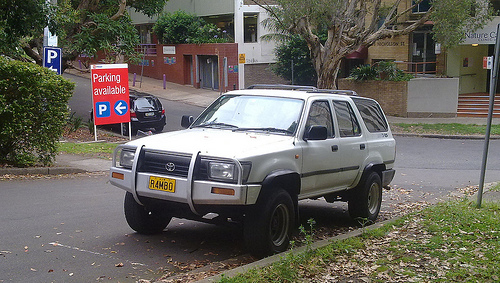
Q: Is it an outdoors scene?
A: Yes, it is outdoors.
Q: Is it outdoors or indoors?
A: It is outdoors.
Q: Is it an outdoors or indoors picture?
A: It is outdoors.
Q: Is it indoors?
A: No, it is outdoors.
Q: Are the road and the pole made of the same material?
A: No, the road is made of concrete and the pole is made of metal.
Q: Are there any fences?
A: No, there are no fences.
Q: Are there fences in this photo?
A: No, there are no fences.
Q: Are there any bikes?
A: No, there are no bikes.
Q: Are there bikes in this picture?
A: No, there are no bikes.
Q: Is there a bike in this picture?
A: No, there are no bikes.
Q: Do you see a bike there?
A: No, there are no bikes.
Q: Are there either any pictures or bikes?
A: No, there are no bikes or pictures.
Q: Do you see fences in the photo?
A: No, there are no fences.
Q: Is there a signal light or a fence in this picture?
A: No, there are no fences or traffic lights.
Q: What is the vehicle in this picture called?
A: The vehicle is a SUV.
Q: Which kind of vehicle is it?
A: The vehicle is a SUV.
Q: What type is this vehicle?
A: This is a SUV.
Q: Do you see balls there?
A: No, there are no balls.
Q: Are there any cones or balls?
A: No, there are no balls or cones.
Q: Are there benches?
A: No, there are no benches.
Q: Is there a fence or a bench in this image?
A: No, there are no benches or fences.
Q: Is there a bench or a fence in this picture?
A: No, there are no benches or fences.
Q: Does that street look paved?
A: Yes, the street is paved.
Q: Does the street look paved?
A: Yes, the street is paved.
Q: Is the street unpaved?
A: No, the street is paved.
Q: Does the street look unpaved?
A: No, the street is paved.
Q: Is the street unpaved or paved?
A: The street is paved.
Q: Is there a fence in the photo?
A: No, there are no fences.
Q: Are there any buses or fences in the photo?
A: No, there are no fences or buses.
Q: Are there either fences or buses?
A: No, there are no fences or buses.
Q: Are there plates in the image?
A: Yes, there is a plate.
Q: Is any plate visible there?
A: Yes, there is a plate.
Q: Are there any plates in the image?
A: Yes, there is a plate.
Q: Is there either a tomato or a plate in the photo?
A: Yes, there is a plate.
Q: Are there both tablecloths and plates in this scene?
A: No, there is a plate but no tablecloths.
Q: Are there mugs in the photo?
A: No, there are no mugs.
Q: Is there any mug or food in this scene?
A: No, there are no mugs or food.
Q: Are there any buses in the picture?
A: No, there are no buses.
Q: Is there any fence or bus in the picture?
A: No, there are no buses or fences.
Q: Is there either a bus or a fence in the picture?
A: No, there are no buses or fences.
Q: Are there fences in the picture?
A: No, there are no fences.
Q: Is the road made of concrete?
A: Yes, the road is made of concrete.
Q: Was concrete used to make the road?
A: Yes, the road is made of concrete.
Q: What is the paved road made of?
A: The road is made of concrete.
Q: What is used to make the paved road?
A: The road is made of concrete.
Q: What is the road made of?
A: The road is made of concrete.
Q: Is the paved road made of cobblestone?
A: No, the road is made of concrete.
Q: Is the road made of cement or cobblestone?
A: The road is made of cement.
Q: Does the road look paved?
A: Yes, the road is paved.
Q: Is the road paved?
A: Yes, the road is paved.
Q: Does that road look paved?
A: Yes, the road is paved.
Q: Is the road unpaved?
A: No, the road is paved.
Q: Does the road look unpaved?
A: No, the road is paved.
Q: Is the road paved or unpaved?
A: The road is paved.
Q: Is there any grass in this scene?
A: Yes, there is grass.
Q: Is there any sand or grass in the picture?
A: Yes, there is grass.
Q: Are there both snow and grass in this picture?
A: No, there is grass but no snow.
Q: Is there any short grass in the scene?
A: Yes, there is short grass.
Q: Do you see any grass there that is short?
A: Yes, there is grass that is short.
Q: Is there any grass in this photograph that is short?
A: Yes, there is grass that is short.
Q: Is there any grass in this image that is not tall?
A: Yes, there is short grass.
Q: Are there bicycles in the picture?
A: No, there are no bicycles.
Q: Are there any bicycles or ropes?
A: No, there are no bicycles or ropes.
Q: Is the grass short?
A: Yes, the grass is short.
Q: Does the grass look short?
A: Yes, the grass is short.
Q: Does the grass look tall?
A: No, the grass is short.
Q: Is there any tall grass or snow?
A: No, there is grass but it is short.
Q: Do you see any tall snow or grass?
A: No, there is grass but it is short.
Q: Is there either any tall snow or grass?
A: No, there is grass but it is short.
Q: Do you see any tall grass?
A: No, there is grass but it is short.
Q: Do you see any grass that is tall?
A: No, there is grass but it is short.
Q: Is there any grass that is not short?
A: No, there is grass but it is short.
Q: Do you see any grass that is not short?
A: No, there is grass but it is short.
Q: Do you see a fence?
A: No, there are no fences.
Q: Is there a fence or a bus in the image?
A: No, there are no fences or buses.